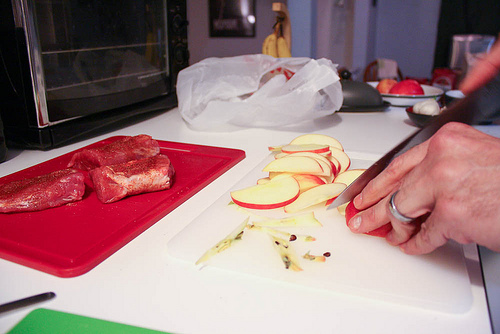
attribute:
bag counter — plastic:
[154, 51, 370, 137]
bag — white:
[176, 55, 358, 128]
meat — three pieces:
[1, 135, 175, 219]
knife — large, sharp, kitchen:
[332, 80, 486, 213]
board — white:
[178, 130, 450, 269]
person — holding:
[348, 36, 499, 255]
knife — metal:
[325, 67, 498, 210]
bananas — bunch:
[256, 9, 295, 59]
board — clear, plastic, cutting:
[173, 152, 460, 315]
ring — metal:
[387, 189, 416, 223]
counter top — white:
[4, 75, 499, 331]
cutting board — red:
[41, 220, 98, 263]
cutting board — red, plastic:
[1, 135, 246, 277]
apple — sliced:
[233, 147, 332, 231]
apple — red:
[231, 175, 302, 207]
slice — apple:
[228, 173, 300, 212]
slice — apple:
[260, 152, 324, 173]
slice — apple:
[281, 180, 348, 215]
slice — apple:
[280, 143, 332, 154]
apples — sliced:
[226, 127, 373, 221]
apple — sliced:
[226, 131, 351, 217]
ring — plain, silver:
[385, 190, 431, 237]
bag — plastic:
[174, 50, 350, 131]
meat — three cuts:
[12, 129, 171, 206]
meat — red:
[0, 130, 177, 216]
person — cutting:
[315, 129, 497, 257]